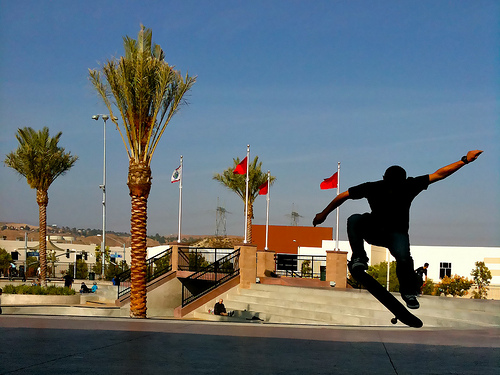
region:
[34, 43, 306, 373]
three palm trees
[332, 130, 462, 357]
skateboarder doing a trick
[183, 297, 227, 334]
man sitting on the step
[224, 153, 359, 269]
three red flags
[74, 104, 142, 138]
three lights attached to the pole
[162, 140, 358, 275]
four flags are flying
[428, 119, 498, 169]
skateboarder is wearing a watch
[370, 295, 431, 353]
skater's foot is not on the board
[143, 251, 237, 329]
walkway for under passage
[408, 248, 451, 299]
skateboarder doing a trick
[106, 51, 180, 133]
Green leaves on top of palm tree.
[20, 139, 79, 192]
Green leaves on top of palm trees.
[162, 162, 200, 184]
Red and white flag on pole.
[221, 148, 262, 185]
Red flag on top of pole.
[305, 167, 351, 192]
Red flag on top of pole.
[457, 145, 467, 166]
Person wearing dark watch on wrist.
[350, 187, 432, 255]
Person wearing black shirt.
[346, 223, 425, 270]
Person wearing dark pants.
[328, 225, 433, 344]
Person doing trick on skateboard.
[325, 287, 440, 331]
Person wearing black and white shoes.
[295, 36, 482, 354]
skateboarder performing a jump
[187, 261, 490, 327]
man on lowest level of cement seating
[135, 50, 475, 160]
faint white streaks of clouds against blue sky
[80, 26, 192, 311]
palm trees with leaves growing straight up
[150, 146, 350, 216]
red and white flag on white poles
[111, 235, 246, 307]
railings surrounding entryway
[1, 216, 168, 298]
park with walls in front of brown hills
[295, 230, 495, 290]
low white building with window and stripes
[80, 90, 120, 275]
three lights on top of tall pole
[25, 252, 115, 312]
people seated near circular planter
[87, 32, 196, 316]
Tall palm tree by sidewalk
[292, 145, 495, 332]
Man jumps on skateboard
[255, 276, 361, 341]
Row of stairs in front of building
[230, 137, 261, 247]
Red flag on a pole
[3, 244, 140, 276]
Group of people standing on sidewalk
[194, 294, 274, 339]
Man sitting on stairs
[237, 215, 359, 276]
Red building roof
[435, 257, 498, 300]
Group of bushes by sidewalk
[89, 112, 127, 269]
Tall street light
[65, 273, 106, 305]
People sitting on stair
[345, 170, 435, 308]
the man is in the air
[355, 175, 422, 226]
the shirt is black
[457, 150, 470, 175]
the watch is black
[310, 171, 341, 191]
the flag is red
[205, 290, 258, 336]
the guy is seated on the stairs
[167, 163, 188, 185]
the flag is white and red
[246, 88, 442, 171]
the sky is cloudless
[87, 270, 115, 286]
the shirt is blue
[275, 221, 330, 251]
the roof is brown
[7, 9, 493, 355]
the scene is outdoors